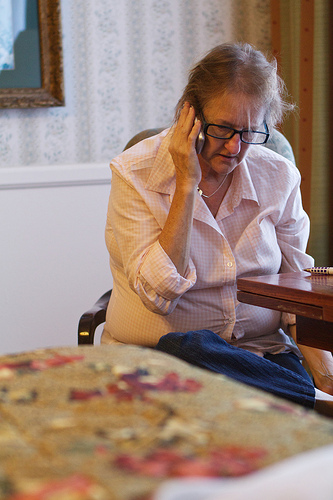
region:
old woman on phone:
[100, 42, 311, 327]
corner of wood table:
[232, 270, 293, 311]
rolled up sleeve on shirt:
[139, 245, 200, 295]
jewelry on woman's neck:
[194, 178, 234, 202]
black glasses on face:
[197, 112, 278, 150]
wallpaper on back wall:
[78, 18, 164, 106]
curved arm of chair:
[72, 299, 117, 338]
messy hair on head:
[243, 58, 297, 113]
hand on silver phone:
[173, 100, 212, 154]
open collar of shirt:
[194, 176, 262, 231]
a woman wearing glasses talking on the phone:
[80, 40, 332, 393]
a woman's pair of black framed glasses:
[202, 118, 272, 145]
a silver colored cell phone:
[176, 97, 210, 156]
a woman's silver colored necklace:
[191, 173, 234, 198]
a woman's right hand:
[167, 100, 205, 189]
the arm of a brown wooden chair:
[77, 287, 111, 344]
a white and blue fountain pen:
[301, 266, 331, 275]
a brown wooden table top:
[235, 270, 332, 322]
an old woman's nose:
[224, 132, 243, 153]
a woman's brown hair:
[187, 32, 292, 115]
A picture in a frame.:
[0, 0, 75, 115]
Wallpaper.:
[63, 0, 184, 100]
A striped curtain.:
[263, 3, 328, 233]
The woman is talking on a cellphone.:
[109, 35, 302, 313]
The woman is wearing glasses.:
[155, 37, 292, 185]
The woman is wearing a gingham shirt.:
[97, 30, 324, 350]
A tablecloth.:
[0, 333, 326, 491]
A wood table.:
[223, 243, 327, 343]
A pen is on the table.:
[289, 251, 331, 278]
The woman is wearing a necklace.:
[157, 33, 282, 215]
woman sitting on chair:
[64, 42, 301, 347]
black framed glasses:
[167, 46, 290, 202]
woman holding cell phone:
[170, 41, 285, 181]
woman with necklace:
[168, 61, 295, 201]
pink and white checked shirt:
[127, 132, 321, 344]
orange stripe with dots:
[291, 6, 327, 153]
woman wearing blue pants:
[162, 33, 329, 410]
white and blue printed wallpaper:
[84, 13, 173, 103]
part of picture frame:
[17, 6, 95, 116]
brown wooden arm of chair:
[67, 286, 112, 345]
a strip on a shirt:
[164, 321, 172, 327]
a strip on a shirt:
[201, 319, 211, 325]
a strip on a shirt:
[187, 307, 188, 327]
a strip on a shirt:
[204, 309, 206, 323]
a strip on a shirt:
[177, 311, 178, 327]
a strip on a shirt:
[136, 308, 137, 323]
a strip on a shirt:
[144, 323, 149, 355]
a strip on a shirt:
[150, 323, 153, 335]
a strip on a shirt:
[253, 313, 257, 322]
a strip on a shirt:
[205, 316, 213, 320]